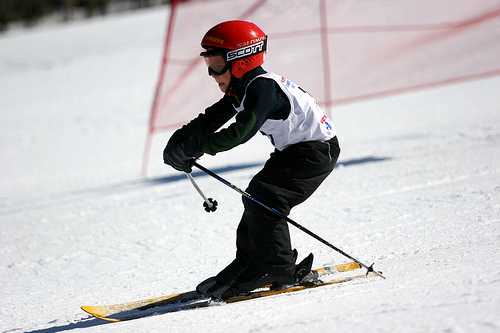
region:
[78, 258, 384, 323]
Children's sized snow skis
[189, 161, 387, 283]
Black and blue ski pole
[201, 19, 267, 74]
Child's sized skiing helmet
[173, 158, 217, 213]
Ski pole being held above ground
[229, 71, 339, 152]
Child's sized white competition jersey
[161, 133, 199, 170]
Small black ski gloves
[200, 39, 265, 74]
Scott red-visor ski goggles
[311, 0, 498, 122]
Red ski course marker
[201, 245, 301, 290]
Black ski boots in bindings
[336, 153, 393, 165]
Shadow cast by course marker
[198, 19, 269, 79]
a red helmet on the boy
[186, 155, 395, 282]
a black ski pole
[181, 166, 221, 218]
a silver ski pole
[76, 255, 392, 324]
a yellow pair of skis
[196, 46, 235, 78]
a pair of goggles on the boy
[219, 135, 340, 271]
a pair of black pants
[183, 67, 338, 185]
a black and white shirt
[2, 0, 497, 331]
white snow on the ground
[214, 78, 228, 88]
the mouth of the boy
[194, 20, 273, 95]
the head of the boy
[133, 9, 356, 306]
Kid is skiing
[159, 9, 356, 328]
Kid has a red helmet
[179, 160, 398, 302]
Snow poles behind the boy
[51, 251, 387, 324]
Skies are yellow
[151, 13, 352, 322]
Helmet is red with black letters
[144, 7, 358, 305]
Boy wears a white vest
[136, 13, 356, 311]
Boy wears a black suit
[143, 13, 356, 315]
Boy is crouched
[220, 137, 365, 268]
Pants are black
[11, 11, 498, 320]
Hill is cover with snow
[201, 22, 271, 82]
red and black plastic helmet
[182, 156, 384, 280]
black and blue ski pole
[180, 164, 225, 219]
black and blue ski pole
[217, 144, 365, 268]
black ski pants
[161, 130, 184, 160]
black ski glove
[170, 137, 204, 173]
black ski glove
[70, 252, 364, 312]
long yellow skinny ski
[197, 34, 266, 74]
Scott orange black and white googles with strap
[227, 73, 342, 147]
white ski vest number identifier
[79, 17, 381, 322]
child skiing downhill with yellow skis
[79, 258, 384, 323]
yellow skis with snow upon them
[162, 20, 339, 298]
child with red helmet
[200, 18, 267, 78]
red helmet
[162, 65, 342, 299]
black snow outfit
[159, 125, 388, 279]
black gloves and ski poles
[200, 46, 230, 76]
ski goggles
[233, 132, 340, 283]
black snow pants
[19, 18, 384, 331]
child and his shadow on a ski slope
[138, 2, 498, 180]
orangeish snow fence